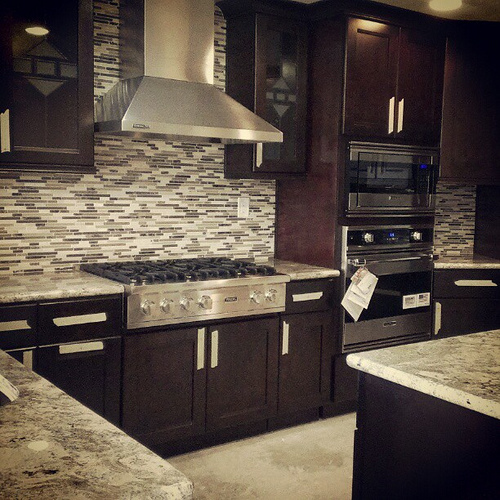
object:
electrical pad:
[236, 197, 251, 218]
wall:
[16, 170, 215, 252]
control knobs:
[138, 302, 151, 314]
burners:
[94, 257, 281, 284]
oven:
[340, 134, 435, 354]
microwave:
[344, 140, 438, 215]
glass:
[358, 152, 424, 208]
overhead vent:
[96, 0, 285, 145]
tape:
[210, 330, 219, 369]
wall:
[403, 134, 432, 161]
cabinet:
[281, 307, 338, 418]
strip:
[278, 320, 290, 355]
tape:
[0, 320, 34, 331]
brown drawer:
[287, 279, 334, 312]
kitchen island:
[345, 327, 499, 498]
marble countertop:
[346, 330, 500, 426]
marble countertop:
[436, 252, 498, 272]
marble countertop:
[268, 260, 340, 281]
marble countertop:
[0, 272, 128, 301]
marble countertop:
[0, 343, 185, 500]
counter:
[0, 346, 190, 500]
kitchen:
[3, 0, 499, 500]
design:
[261, 25, 301, 160]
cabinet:
[221, 0, 316, 180]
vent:
[95, 0, 282, 146]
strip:
[197, 328, 205, 370]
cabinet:
[0, 290, 127, 442]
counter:
[341, 328, 500, 429]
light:
[421, 0, 465, 21]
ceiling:
[476, 4, 492, 22]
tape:
[451, 276, 498, 288]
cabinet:
[433, 265, 498, 341]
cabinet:
[117, 322, 205, 445]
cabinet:
[204, 316, 279, 433]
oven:
[72, 256, 289, 329]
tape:
[52, 313, 108, 326]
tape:
[290, 290, 324, 303]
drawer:
[0, 290, 121, 347]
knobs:
[159, 298, 172, 313]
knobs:
[180, 297, 191, 310]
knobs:
[199, 294, 214, 309]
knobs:
[249, 290, 264, 306]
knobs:
[265, 287, 279, 302]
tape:
[387, 95, 395, 135]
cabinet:
[309, 11, 446, 147]